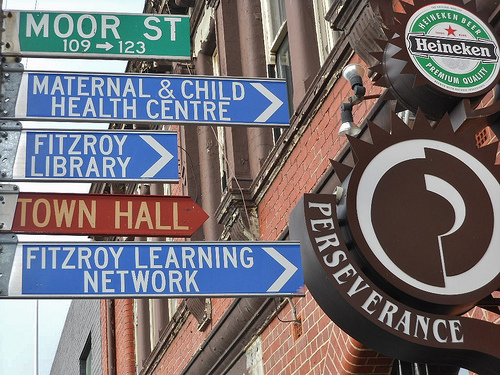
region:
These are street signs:
[49, 19, 246, 360]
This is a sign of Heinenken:
[388, 24, 472, 76]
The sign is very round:
[393, 21, 435, 114]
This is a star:
[440, 19, 457, 39]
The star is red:
[441, 17, 461, 46]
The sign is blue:
[47, 232, 296, 341]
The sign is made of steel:
[31, 74, 146, 141]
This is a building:
[209, 311, 322, 371]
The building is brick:
[238, 345, 368, 370]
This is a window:
[263, 27, 340, 102]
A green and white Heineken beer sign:
[353, 2, 498, 153]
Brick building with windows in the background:
[10, 300, 312, 372]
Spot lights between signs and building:
[310, 61, 380, 154]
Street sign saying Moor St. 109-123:
[8, 8, 247, 63]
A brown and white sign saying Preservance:
[291, 125, 497, 369]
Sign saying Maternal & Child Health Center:
[0, 64, 308, 124]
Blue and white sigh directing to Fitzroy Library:
[17, 132, 229, 190]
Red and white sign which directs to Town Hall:
[8, 188, 229, 239]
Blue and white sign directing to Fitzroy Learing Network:
[16, 240, 332, 309]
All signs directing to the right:
[106, 73, 321, 310]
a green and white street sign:
[20, 9, 191, 61]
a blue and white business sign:
[32, 77, 288, 131]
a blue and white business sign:
[28, 132, 170, 181]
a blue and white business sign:
[23, 244, 305, 304]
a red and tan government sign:
[20, 191, 203, 243]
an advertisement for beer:
[403, 2, 498, 90]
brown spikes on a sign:
[349, 110, 489, 140]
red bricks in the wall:
[277, 334, 308, 362]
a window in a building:
[252, 5, 302, 110]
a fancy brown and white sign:
[300, 123, 495, 345]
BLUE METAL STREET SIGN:
[12, 236, 322, 303]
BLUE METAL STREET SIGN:
[12, 132, 182, 173]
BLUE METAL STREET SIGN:
[27, 68, 289, 130]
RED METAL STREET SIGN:
[27, 181, 223, 233]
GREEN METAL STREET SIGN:
[1, 23, 192, 58]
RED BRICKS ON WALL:
[209, 174, 357, 334]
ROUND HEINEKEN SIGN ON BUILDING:
[401, 8, 485, 79]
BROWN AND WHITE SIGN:
[284, 137, 499, 348]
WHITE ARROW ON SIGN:
[258, 238, 313, 310]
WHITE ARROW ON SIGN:
[137, 139, 176, 189]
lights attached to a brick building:
[330, 60, 388, 138]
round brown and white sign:
[325, 104, 499, 318]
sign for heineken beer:
[396, 5, 498, 100]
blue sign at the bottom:
[8, 238, 315, 303]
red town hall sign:
[10, 190, 210, 242]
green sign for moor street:
[4, 6, 201, 68]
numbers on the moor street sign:
[60, 37, 160, 58]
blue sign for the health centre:
[20, 63, 300, 130]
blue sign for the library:
[15, 125, 201, 192]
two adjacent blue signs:
[11, 66, 311, 183]